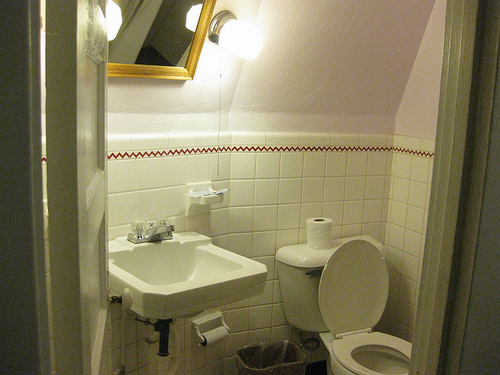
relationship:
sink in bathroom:
[117, 246, 271, 306] [72, 126, 477, 371]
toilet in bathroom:
[323, 318, 428, 374] [72, 126, 477, 371]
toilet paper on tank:
[300, 214, 335, 244] [287, 231, 343, 327]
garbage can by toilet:
[233, 337, 315, 375] [323, 318, 428, 374]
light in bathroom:
[213, 6, 292, 71] [72, 126, 477, 371]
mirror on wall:
[107, 9, 210, 84] [125, 0, 432, 214]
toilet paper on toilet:
[300, 214, 335, 244] [323, 318, 428, 374]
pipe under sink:
[151, 327, 173, 362] [117, 246, 271, 306]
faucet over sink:
[126, 216, 183, 245] [117, 246, 271, 306]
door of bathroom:
[59, 21, 123, 324] [72, 126, 477, 371]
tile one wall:
[255, 156, 391, 233] [125, 0, 432, 214]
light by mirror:
[213, 6, 292, 71] [107, 9, 210, 84]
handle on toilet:
[303, 262, 323, 284] [323, 318, 428, 374]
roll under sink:
[204, 324, 233, 347] [117, 246, 271, 306]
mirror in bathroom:
[107, 9, 210, 84] [72, 126, 477, 371]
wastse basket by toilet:
[233, 337, 315, 375] [323, 318, 428, 374]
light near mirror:
[213, 6, 292, 71] [107, 9, 210, 84]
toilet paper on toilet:
[305, 217, 333, 251] [323, 318, 428, 374]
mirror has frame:
[107, 9, 210, 84] [102, 62, 205, 83]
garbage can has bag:
[233, 337, 315, 375] [263, 349, 301, 366]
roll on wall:
[204, 324, 233, 347] [125, 0, 432, 214]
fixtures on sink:
[128, 222, 169, 235] [117, 246, 271, 306]